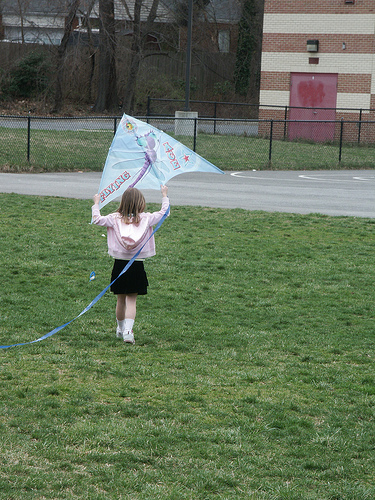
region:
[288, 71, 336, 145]
Faded red set of doors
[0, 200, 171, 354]
Long blue tail of the kite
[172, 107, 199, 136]
Cement base of the pole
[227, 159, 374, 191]
White circles on the asphalt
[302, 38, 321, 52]
Black and clear light above the door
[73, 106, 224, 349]
Small girl holding a large kite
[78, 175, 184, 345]
Girl dressed in pink, black, and white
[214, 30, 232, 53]
Window of the building in the background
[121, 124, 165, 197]
Purple dragonfly cartoon character on the kite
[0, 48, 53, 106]
Dark green bush behind the fence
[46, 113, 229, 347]
A young girl holding a kite.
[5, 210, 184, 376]
The long blue tail of a kite.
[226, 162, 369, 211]
White lines painted on asphalt.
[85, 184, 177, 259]
Girl wearing a pink jacket.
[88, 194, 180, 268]
A long sleeve pink jacket.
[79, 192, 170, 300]
Girl wearing a black skirt.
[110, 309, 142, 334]
A pair of white socks.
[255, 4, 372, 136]
A red and white brick building.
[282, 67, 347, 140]
Double doors on a building.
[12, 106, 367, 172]
A black chain link fence.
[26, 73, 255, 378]
Girl holding a kite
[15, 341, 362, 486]
Ground covered in grass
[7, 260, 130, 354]
Kite has a long blue tail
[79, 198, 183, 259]
Girl wearing pink hooded sweatshirt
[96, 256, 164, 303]
Girl wearing a black skirt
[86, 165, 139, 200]
The kite says the word Flying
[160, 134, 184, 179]
The kite says the word Ace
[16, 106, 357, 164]
A chainlink fence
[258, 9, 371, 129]
Building made of brick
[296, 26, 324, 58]
Light over the red door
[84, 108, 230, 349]
a little girl carrying a kite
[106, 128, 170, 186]
the kite has an image of a dragonfly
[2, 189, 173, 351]
the kite has a long blue tail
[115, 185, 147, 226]
the little girl has blond hair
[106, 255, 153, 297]
the little girl is wearing a black skirt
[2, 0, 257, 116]
most of the trees in the background have no leaves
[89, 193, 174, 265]
the girl wears a pink hooded jacket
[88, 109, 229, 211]
the kite is blue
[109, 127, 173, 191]
the dragonfly on the kite is purple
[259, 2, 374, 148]
a brick building in the background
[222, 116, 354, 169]
a black chainlink fence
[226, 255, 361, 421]
a patch of green grass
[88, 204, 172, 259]
a pink hoody jacket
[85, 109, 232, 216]
a kite with a dragonfly on it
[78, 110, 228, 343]
a girl flying a kite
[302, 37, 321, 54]
a lamp light on a wall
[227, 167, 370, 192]
painted lines on a basketball court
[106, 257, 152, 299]
a black knee high skirt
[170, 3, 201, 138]
a light pole in the ground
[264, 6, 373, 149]
a striped brick building